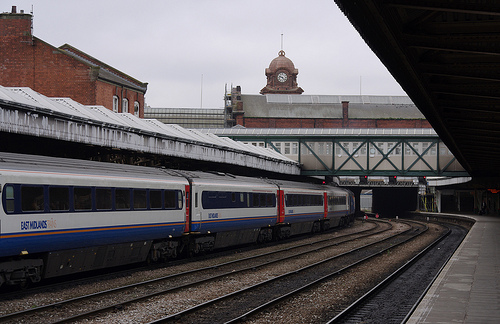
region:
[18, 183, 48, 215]
The window is square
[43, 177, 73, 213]
The window is square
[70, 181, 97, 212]
The window is square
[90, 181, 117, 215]
The window is square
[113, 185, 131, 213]
The window is square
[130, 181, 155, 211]
The window is square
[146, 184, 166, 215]
The window is square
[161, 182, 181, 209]
The window is square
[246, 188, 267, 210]
The window is square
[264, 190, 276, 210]
The window is square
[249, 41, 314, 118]
a clock on top of the building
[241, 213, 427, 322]
the tracks for the trains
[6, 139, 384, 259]
the cars of the train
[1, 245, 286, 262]
the wheels on the train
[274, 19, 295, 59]
the top of the clock with a metal pole sticking out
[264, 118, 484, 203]
the walkway above the tracks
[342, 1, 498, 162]
canopy over the area to wait for train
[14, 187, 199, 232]
the windows on the train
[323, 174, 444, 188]
the lights for the trains to go or stop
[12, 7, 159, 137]
red brick building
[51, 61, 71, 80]
the building is brown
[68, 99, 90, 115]
the roof is white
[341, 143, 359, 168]
the bridge is green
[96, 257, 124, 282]
the train is on the track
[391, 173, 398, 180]
the light is red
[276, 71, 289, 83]
the clock is on the building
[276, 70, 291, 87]
A clock on a tower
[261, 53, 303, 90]
A clock tower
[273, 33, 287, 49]
The pole sticking out of the clock tower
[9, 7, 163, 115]
The brick building next to the train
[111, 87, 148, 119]
The windows on the brick building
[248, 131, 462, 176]
The green crosses on the bridhe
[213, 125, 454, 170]
A walking bridge above the train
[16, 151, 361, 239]
A train that is stopped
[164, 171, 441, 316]
The tracks of the train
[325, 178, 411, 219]
The tunnel the train went through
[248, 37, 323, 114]
tall clock on tower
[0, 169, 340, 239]
grey and blue train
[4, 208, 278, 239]
orange stripe on train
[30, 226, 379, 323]
train on black tracks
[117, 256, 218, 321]
grey gravel on tracks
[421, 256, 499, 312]
grey sidewalk near tracks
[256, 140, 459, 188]
green bridge over tracks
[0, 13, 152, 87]
red brick building over train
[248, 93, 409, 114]
grey roof under clock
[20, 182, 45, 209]
A window on a vehicle.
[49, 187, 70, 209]
A window on a vehicle.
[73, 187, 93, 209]
A window on a vehicle.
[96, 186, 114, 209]
A window on a vehicle.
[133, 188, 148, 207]
A window on a vehicle.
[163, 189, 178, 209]
A window on a vehicle.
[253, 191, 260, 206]
A window on a vehicle.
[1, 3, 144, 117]
A building in a city.